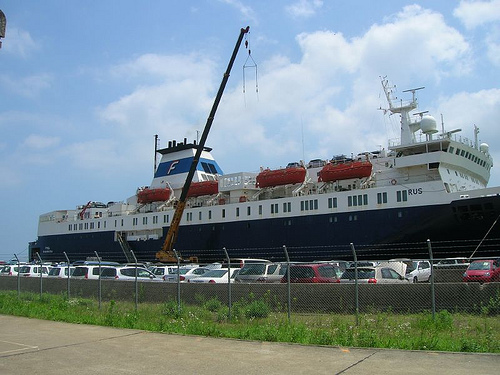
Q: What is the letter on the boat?
A: F.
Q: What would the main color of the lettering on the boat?
A: White.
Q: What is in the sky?
A: Clouds.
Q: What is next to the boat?
A: Cranes.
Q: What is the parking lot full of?
A: Cars.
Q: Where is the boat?
A: Next to the parking lot.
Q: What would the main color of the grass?
A: Green.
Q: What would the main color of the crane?
A: Yellow.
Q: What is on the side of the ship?
A: A line of rowboats.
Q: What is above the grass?
A: A fence next to the parking lot.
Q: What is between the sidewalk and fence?
A: The grass on the ground.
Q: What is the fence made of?
A: Wire.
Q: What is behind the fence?
A: Cars.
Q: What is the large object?
A: Ship.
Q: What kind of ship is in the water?
A: Cargo.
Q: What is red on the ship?
A: Life rafts.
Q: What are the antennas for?
A: Radio equipment.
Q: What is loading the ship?
A: Crane.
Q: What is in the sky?
A: Clouds.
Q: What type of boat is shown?
A: A cruise ship.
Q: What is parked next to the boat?
A: Cars.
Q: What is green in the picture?
A: Grass.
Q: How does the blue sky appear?
A: Cloudy.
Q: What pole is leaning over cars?
A: Construction pole.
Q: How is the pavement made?
A: Of stone.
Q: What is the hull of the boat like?
A: Navy blue.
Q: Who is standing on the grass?
A: No one.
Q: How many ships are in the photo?
A: One.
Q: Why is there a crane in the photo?
A: Offloading.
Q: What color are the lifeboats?
A: Red.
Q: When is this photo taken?
A: Daytime.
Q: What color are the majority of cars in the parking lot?
A: White.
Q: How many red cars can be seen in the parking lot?
A: Two.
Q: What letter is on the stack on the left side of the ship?
A: F.